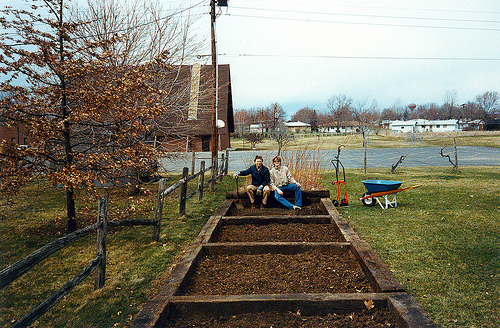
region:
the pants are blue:
[273, 182, 302, 200]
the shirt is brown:
[268, 167, 298, 182]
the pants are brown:
[246, 186, 271, 203]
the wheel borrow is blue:
[361, 177, 405, 187]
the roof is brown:
[198, 73, 205, 120]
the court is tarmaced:
[403, 141, 438, 165]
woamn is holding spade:
[228, 156, 270, 210]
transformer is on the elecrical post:
[205, 1, 233, 21]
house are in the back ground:
[381, 117, 466, 141]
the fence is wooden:
[158, 169, 205, 214]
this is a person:
[240, 143, 269, 210]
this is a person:
[274, 138, 306, 217]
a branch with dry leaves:
[34, 148, 99, 233]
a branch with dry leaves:
[71, 125, 162, 195]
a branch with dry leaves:
[77, 100, 149, 147]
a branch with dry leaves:
[82, 73, 189, 130]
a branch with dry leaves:
[73, 28, 133, 70]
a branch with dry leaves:
[4, 143, 71, 195]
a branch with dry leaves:
[128, 71, 197, 135]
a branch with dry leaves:
[79, 68, 152, 115]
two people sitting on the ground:
[229, 143, 315, 217]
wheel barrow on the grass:
[350, 173, 420, 212]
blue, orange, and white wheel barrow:
[355, 168, 420, 212]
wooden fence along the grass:
[1, 125, 239, 325]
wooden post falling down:
[98, 214, 160, 229]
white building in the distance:
[382, 113, 465, 135]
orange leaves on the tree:
[0, 0, 224, 245]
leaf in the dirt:
[361, 297, 378, 313]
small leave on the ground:
[98, 282, 137, 326]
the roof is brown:
[63, 64, 233, 136]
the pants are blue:
[270, 184, 305, 209]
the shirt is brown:
[273, 168, 287, 178]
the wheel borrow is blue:
[361, 176, 402, 191]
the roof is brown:
[193, 75, 230, 120]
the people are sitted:
[241, 157, 303, 211]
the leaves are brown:
[92, 73, 142, 139]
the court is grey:
[401, 141, 434, 162]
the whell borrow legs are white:
[374, 197, 404, 209]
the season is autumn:
[6, 6, 496, 326]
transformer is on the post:
[213, 0, 232, 9]